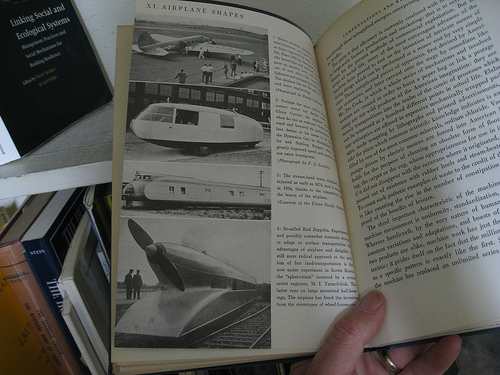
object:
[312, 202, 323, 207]
word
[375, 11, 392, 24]
word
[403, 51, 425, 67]
word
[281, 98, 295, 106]
word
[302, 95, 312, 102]
word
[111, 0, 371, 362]
page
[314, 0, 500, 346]
page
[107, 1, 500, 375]
book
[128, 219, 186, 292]
propeller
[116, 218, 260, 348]
plane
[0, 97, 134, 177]
surface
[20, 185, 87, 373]
book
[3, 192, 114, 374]
binder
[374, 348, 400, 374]
ring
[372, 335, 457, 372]
person's finger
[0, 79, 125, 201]
table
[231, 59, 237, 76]
person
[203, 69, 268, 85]
sidewalk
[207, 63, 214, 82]
person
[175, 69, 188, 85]
person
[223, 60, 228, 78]
person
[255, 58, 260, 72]
person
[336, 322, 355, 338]
grooves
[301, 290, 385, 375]
thumb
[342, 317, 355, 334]
grooves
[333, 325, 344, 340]
grooves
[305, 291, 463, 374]
hand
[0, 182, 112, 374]
shelf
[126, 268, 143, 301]
men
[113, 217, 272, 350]
photograph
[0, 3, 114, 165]
black book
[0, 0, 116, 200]
shelf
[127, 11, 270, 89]
photograph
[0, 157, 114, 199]
front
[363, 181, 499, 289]
paragraph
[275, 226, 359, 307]
paragraph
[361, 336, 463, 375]
fingers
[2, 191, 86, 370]
book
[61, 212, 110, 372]
book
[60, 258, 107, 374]
book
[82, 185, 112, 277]
book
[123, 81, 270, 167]
photograph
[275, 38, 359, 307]
text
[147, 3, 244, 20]
text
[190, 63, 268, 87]
ramp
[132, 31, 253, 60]
airplane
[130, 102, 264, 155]
vehicle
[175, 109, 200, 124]
windows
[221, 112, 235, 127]
windows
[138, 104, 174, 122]
windows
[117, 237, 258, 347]
train body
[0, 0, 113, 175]
empty space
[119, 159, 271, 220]
photograph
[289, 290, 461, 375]
person